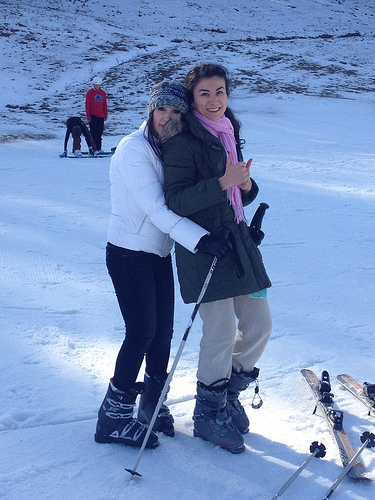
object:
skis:
[300, 369, 368, 479]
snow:
[273, 110, 374, 338]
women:
[164, 63, 273, 457]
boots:
[95, 378, 158, 447]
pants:
[197, 291, 270, 384]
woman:
[95, 82, 233, 449]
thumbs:
[246, 159, 253, 169]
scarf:
[193, 109, 246, 223]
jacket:
[107, 120, 209, 256]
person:
[85, 77, 108, 154]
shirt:
[86, 88, 107, 120]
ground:
[0, 0, 375, 99]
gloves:
[196, 234, 233, 258]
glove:
[250, 228, 265, 246]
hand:
[225, 152, 250, 189]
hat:
[148, 80, 188, 113]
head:
[187, 63, 227, 121]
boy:
[64, 116, 96, 151]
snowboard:
[68, 156, 106, 158]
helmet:
[93, 77, 102, 85]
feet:
[194, 381, 244, 447]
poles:
[324, 433, 375, 499]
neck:
[148, 125, 162, 150]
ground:
[1, 93, 374, 498]